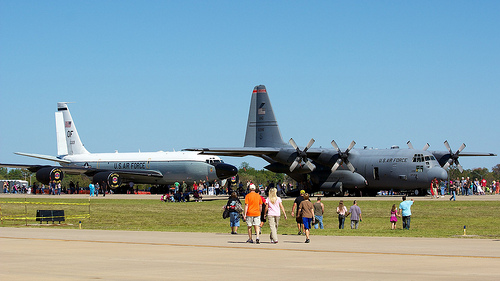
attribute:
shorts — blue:
[303, 218, 313, 231]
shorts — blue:
[230, 212, 240, 227]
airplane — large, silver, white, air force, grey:
[14, 102, 238, 195]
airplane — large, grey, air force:
[182, 83, 496, 198]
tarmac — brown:
[1, 226, 500, 281]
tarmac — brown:
[2, 192, 500, 202]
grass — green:
[1, 196, 499, 239]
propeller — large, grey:
[288, 138, 316, 172]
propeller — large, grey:
[332, 138, 357, 173]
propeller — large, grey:
[441, 140, 467, 174]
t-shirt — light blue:
[399, 200, 414, 217]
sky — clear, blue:
[2, 0, 500, 172]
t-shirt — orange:
[243, 192, 264, 218]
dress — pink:
[389, 205, 398, 224]